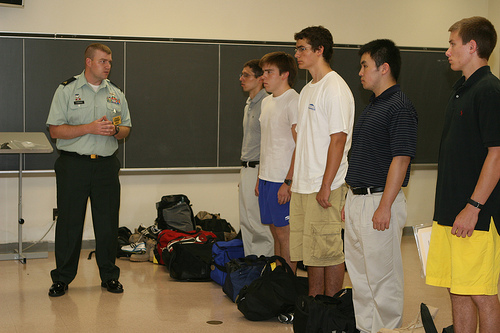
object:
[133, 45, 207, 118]
portion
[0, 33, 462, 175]
chalkboard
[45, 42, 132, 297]
officer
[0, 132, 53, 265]
podium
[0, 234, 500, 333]
floor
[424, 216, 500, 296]
shorts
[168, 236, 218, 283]
duffle bag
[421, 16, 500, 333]
recruit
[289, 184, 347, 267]
shorts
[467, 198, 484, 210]
band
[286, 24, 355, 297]
man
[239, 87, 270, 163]
shirt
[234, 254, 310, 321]
bag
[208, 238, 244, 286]
bag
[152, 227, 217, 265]
bag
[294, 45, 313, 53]
glasses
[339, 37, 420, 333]
person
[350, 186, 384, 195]
belt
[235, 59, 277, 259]
man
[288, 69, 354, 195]
shirt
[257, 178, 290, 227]
shorts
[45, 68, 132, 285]
uniform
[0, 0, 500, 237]
wall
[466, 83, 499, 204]
arm